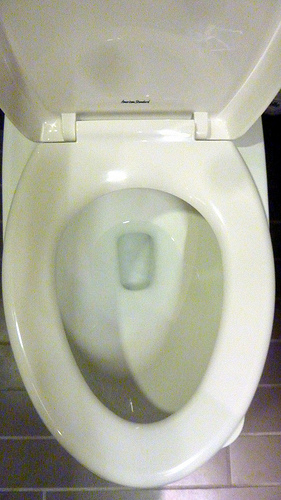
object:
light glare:
[102, 168, 131, 186]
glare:
[158, 355, 281, 498]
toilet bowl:
[54, 191, 221, 426]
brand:
[119, 95, 153, 109]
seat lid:
[0, 2, 280, 143]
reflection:
[150, 208, 190, 246]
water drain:
[113, 231, 158, 290]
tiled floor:
[0, 96, 280, 499]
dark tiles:
[0, 345, 167, 499]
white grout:
[1, 460, 78, 493]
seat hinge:
[193, 111, 211, 139]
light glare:
[155, 126, 188, 145]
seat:
[5, 120, 274, 491]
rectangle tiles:
[226, 431, 279, 491]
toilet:
[56, 113, 79, 145]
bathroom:
[0, 0, 281, 497]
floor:
[1, 111, 279, 498]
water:
[50, 184, 224, 427]